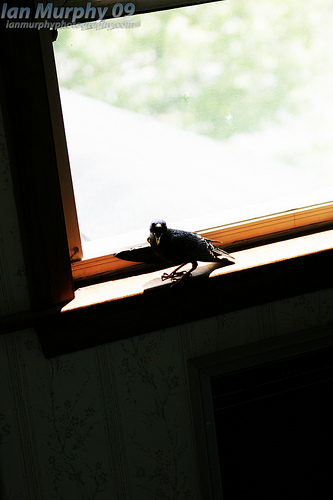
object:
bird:
[146, 217, 236, 289]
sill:
[30, 201, 332, 366]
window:
[2, 1, 332, 362]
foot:
[160, 270, 187, 281]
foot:
[169, 273, 193, 289]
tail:
[206, 239, 235, 265]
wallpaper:
[0, 355, 203, 500]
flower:
[143, 353, 152, 365]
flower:
[168, 363, 175, 374]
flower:
[84, 405, 99, 418]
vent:
[184, 315, 333, 500]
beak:
[154, 233, 162, 245]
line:
[94, 340, 122, 500]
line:
[3, 328, 30, 500]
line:
[190, 321, 197, 358]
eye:
[153, 232, 156, 236]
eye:
[160, 232, 163, 236]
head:
[149, 217, 168, 246]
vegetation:
[52, 1, 332, 143]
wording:
[0, 1, 136, 33]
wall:
[0, 0, 332, 499]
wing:
[177, 238, 222, 264]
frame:
[0, 0, 75, 316]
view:
[48, 0, 332, 263]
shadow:
[143, 257, 235, 289]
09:
[111, 1, 137, 19]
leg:
[161, 258, 190, 281]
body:
[146, 228, 212, 266]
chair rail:
[0, 305, 35, 336]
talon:
[163, 272, 170, 275]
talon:
[161, 275, 169, 281]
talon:
[170, 276, 179, 281]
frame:
[39, 25, 83, 263]